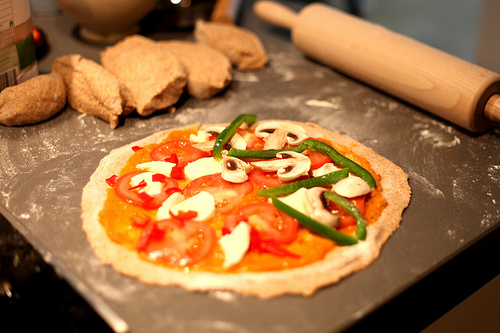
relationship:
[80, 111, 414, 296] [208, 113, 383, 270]
pizza has vegetables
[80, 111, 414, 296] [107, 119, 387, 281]
pizza has tomato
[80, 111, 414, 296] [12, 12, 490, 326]
pizza on a counter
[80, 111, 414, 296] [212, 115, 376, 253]
pizza with peppers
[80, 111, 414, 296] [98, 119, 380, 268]
pizza with toppings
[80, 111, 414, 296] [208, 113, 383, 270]
pizza with vegetables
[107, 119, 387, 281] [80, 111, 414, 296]
tomatoes on a pizza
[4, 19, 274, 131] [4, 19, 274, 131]
lumps of lumps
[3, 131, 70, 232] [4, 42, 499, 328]
flour on surface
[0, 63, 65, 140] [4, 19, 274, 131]
lump of lumps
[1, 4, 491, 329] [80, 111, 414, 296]
photo of pizza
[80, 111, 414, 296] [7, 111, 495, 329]
pizza in foreground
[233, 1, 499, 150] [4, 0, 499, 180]
roller in background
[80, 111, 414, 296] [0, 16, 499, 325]
pizza on surface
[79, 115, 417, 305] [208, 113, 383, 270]
dough with vegetables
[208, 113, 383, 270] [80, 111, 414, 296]
vegetables on pizza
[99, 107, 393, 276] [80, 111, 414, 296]
toppings on pizza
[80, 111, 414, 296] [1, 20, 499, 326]
pizza on counter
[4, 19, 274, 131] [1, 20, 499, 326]
lumps on counter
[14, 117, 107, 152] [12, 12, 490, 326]
flour on counter